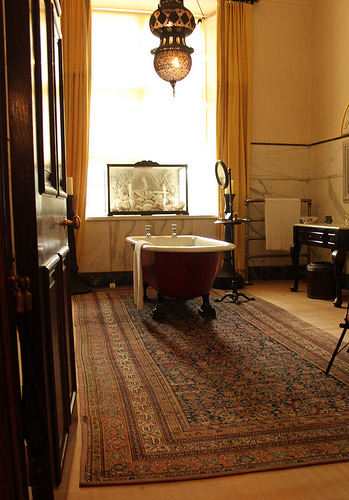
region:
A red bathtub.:
[122, 221, 238, 322]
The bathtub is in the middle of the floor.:
[119, 218, 236, 335]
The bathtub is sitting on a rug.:
[112, 220, 237, 328]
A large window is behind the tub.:
[77, 1, 214, 227]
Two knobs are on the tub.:
[139, 219, 189, 237]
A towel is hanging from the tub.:
[112, 233, 170, 318]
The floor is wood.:
[252, 477, 336, 498]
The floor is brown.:
[258, 474, 344, 496]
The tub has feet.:
[127, 218, 228, 321]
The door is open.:
[5, 127, 89, 465]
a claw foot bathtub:
[122, 219, 230, 332]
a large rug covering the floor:
[43, 268, 343, 495]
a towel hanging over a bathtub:
[120, 224, 154, 318]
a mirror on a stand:
[214, 144, 236, 205]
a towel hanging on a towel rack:
[228, 182, 312, 276]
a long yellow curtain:
[200, 95, 258, 305]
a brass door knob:
[46, 210, 88, 249]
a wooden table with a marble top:
[263, 207, 344, 302]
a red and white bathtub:
[111, 226, 231, 316]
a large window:
[57, 98, 230, 245]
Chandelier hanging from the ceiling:
[133, 0, 211, 106]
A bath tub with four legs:
[122, 217, 244, 338]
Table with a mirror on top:
[209, 160, 253, 313]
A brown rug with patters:
[68, 281, 344, 489]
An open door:
[0, 12, 107, 497]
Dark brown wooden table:
[288, 208, 347, 307]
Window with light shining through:
[53, 3, 254, 283]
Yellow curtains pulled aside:
[51, 0, 117, 278]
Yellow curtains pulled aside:
[199, 0, 265, 290]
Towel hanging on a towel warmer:
[241, 192, 316, 289]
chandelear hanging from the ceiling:
[126, 4, 226, 102]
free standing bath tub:
[115, 213, 241, 335]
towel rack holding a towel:
[240, 189, 320, 288]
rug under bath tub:
[72, 288, 320, 457]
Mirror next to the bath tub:
[214, 155, 238, 303]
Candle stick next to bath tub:
[217, 180, 244, 289]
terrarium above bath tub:
[96, 156, 208, 219]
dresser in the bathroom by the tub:
[276, 193, 348, 330]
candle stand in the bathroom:
[61, 172, 90, 300]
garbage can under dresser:
[291, 245, 347, 317]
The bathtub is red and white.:
[117, 221, 235, 324]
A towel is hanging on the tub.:
[119, 228, 169, 316]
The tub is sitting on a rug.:
[71, 221, 347, 491]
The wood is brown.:
[266, 475, 346, 495]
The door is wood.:
[15, 131, 86, 486]